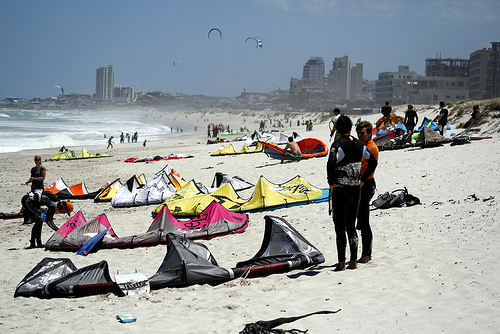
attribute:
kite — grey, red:
[13, 214, 323, 299]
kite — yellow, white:
[155, 170, 317, 222]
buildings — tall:
[229, 60, 453, 124]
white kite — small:
[256, 35, 263, 50]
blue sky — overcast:
[1, 0, 498, 100]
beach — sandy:
[15, 125, 486, 330]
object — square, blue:
[117, 312, 138, 323]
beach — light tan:
[1, 103, 497, 332]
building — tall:
[84, 41, 144, 125]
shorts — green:
[282, 149, 302, 159]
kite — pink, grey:
[43, 203, 245, 245]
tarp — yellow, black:
[152, 172, 329, 219]